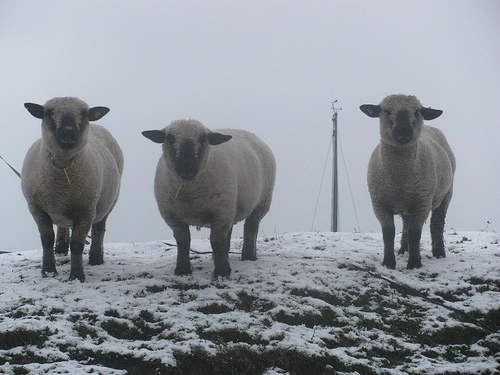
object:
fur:
[366, 95, 453, 241]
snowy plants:
[307, 223, 403, 323]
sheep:
[141, 93, 456, 283]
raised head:
[358, 93, 443, 149]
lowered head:
[140, 119, 232, 180]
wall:
[202, 56, 314, 113]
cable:
[160, 241, 498, 334]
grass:
[0, 264, 500, 375]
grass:
[0, 231, 497, 370]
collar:
[43, 150, 81, 185]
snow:
[0, 232, 499, 375]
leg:
[241, 213, 262, 261]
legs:
[376, 209, 429, 270]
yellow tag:
[175, 184, 182, 200]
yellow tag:
[64, 168, 72, 185]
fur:
[142, 118, 276, 277]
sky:
[0, 0, 500, 256]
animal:
[358, 93, 456, 270]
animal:
[141, 118, 276, 280]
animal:
[20, 96, 125, 282]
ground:
[0, 263, 499, 373]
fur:
[19, 96, 118, 232]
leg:
[429, 209, 447, 258]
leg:
[209, 213, 234, 282]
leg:
[172, 226, 192, 277]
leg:
[406, 210, 426, 270]